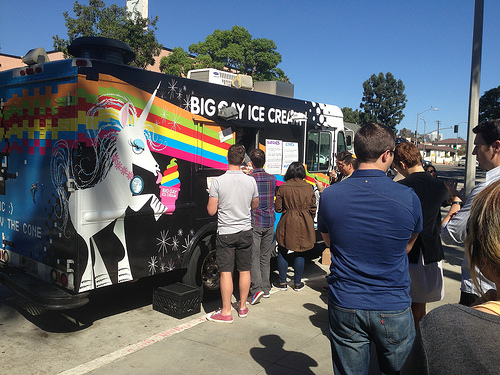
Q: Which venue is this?
A: This is a pavement.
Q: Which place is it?
A: It is a pavement.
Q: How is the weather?
A: It is clear.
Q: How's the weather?
A: It is clear.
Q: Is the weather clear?
A: Yes, it is clear.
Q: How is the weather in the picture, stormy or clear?
A: It is clear.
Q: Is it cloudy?
A: No, it is clear.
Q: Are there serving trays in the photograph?
A: No, there are no serving trays.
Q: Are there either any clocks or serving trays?
A: No, there are no serving trays or clocks.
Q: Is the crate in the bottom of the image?
A: Yes, the crate is in the bottom of the image.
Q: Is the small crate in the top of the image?
A: No, the crate is in the bottom of the image.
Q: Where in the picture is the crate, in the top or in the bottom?
A: The crate is in the bottom of the image.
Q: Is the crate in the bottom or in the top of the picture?
A: The crate is in the bottom of the image.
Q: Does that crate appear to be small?
A: Yes, the crate is small.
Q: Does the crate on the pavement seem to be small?
A: Yes, the crate is small.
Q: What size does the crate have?
A: The crate has small size.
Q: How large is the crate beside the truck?
A: The crate is small.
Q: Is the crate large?
A: No, the crate is small.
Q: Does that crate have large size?
A: No, the crate is small.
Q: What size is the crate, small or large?
A: The crate is small.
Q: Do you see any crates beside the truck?
A: Yes, there is a crate beside the truck.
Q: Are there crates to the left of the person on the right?
A: Yes, there is a crate to the left of the person.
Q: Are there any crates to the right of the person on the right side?
A: No, the crate is to the left of the person.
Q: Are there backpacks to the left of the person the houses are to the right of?
A: No, there is a crate to the left of the person.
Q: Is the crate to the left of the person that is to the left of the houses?
A: Yes, the crate is to the left of the person.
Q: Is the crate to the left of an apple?
A: No, the crate is to the left of the person.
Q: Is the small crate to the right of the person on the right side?
A: No, the crate is to the left of the person.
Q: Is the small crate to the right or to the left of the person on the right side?
A: The crate is to the left of the person.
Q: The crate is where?
A: The crate is on the pavement.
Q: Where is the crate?
A: The crate is on the pavement.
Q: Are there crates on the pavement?
A: Yes, there is a crate on the pavement.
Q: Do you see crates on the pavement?
A: Yes, there is a crate on the pavement.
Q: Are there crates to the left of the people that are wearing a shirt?
A: Yes, there is a crate to the left of the people.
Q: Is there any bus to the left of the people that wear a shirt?
A: No, there is a crate to the left of the people.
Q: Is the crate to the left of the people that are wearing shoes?
A: Yes, the crate is to the left of the people.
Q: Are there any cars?
A: No, there are no cars.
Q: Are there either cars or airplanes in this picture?
A: No, there are no cars or airplanes.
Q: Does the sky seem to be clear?
A: Yes, the sky is clear.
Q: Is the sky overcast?
A: No, the sky is clear.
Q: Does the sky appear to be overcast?
A: No, the sky is clear.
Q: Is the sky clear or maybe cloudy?
A: The sky is clear.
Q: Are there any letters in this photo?
A: Yes, there are letters.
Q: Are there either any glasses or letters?
A: Yes, there are letters.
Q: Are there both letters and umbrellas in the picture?
A: No, there are letters but no umbrellas.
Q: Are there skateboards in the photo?
A: No, there are no skateboards.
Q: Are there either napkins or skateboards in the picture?
A: No, there are no skateboards or napkins.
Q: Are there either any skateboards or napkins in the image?
A: No, there are no skateboards or napkins.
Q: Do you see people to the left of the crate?
A: No, the person is to the right of the crate.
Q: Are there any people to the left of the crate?
A: No, the person is to the right of the crate.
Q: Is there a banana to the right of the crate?
A: No, there is a person to the right of the crate.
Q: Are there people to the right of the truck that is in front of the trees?
A: Yes, there is a person to the right of the truck.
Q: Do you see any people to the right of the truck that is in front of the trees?
A: Yes, there is a person to the right of the truck.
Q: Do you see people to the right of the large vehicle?
A: Yes, there is a person to the right of the truck.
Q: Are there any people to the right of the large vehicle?
A: Yes, there is a person to the right of the truck.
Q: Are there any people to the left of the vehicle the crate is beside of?
A: No, the person is to the right of the truck.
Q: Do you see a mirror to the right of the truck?
A: No, there is a person to the right of the truck.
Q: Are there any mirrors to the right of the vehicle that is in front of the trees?
A: No, there is a person to the right of the truck.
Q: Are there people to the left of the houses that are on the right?
A: Yes, there is a person to the left of the houses.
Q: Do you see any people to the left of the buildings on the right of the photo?
A: Yes, there is a person to the left of the houses.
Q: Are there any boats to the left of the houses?
A: No, there is a person to the left of the houses.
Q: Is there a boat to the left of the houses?
A: No, there is a person to the left of the houses.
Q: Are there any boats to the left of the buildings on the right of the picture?
A: No, there is a person to the left of the houses.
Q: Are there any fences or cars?
A: No, there are no cars or fences.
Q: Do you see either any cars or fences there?
A: No, there are no cars or fences.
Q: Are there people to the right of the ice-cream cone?
A: Yes, there is a person to the right of the ice-cream cone.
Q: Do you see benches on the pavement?
A: No, there is a person on the pavement.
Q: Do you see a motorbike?
A: No, there are no motorcycles.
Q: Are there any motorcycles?
A: No, there are no motorcycles.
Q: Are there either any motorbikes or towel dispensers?
A: No, there are no motorbikes or towel dispensers.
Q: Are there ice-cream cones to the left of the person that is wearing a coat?
A: Yes, there is an ice-cream cone to the left of the person.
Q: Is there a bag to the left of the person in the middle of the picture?
A: No, there is an ice-cream cone to the left of the person.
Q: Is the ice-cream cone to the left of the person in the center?
A: Yes, the ice-cream cone is to the left of the person.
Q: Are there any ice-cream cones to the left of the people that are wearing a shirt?
A: Yes, there is an ice-cream cone to the left of the people.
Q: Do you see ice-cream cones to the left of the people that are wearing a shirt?
A: Yes, there is an ice-cream cone to the left of the people.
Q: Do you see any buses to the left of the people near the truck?
A: No, there is an ice-cream cone to the left of the people.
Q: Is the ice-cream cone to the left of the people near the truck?
A: Yes, the ice-cream cone is to the left of the people.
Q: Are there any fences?
A: No, there are no fences.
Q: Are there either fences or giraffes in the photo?
A: No, there are no fences or giraffes.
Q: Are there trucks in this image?
A: Yes, there is a truck.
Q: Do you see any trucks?
A: Yes, there is a truck.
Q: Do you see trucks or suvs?
A: Yes, there is a truck.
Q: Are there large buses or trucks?
A: Yes, there is a large truck.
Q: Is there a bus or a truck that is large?
A: Yes, the truck is large.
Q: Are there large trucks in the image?
A: Yes, there is a large truck.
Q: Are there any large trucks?
A: Yes, there is a large truck.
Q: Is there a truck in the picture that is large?
A: Yes, there is a truck that is large.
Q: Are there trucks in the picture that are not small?
A: Yes, there is a large truck.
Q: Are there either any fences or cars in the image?
A: No, there are no cars or fences.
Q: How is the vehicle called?
A: The vehicle is a truck.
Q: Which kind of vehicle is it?
A: The vehicle is a truck.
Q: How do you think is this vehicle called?
A: This is a truck.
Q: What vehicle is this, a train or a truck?
A: This is a truck.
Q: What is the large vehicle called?
A: The vehicle is a truck.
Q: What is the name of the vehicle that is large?
A: The vehicle is a truck.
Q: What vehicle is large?
A: The vehicle is a truck.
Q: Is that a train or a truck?
A: That is a truck.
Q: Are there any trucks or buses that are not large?
A: No, there is a truck but it is large.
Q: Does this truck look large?
A: Yes, the truck is large.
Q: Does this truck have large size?
A: Yes, the truck is large.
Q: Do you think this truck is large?
A: Yes, the truck is large.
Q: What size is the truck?
A: The truck is large.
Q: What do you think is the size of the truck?
A: The truck is large.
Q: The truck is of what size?
A: The truck is large.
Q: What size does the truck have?
A: The truck has large size.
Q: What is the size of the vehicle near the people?
A: The truck is large.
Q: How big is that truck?
A: The truck is large.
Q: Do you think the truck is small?
A: No, the truck is large.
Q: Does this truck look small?
A: No, the truck is large.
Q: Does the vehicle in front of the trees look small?
A: No, the truck is large.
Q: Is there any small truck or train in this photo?
A: No, there is a truck but it is large.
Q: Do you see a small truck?
A: No, there is a truck but it is large.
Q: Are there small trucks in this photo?
A: No, there is a truck but it is large.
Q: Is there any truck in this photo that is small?
A: No, there is a truck but it is large.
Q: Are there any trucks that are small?
A: No, there is a truck but it is large.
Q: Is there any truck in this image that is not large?
A: No, there is a truck but it is large.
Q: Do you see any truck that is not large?
A: No, there is a truck but it is large.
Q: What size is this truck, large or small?
A: The truck is large.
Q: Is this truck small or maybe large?
A: The truck is large.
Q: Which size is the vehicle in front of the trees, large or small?
A: The truck is large.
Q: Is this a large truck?
A: Yes, this is a large truck.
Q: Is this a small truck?
A: No, this is a large truck.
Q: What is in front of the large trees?
A: The truck is in front of the trees.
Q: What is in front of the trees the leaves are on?
A: The truck is in front of the trees.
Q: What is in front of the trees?
A: The truck is in front of the trees.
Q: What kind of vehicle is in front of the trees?
A: The vehicle is a truck.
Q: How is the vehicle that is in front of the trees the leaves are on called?
A: The vehicle is a truck.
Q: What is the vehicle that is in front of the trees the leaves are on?
A: The vehicle is a truck.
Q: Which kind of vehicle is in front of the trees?
A: The vehicle is a truck.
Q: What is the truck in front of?
A: The truck is in front of the trees.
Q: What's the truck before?
A: The truck is in front of the trees.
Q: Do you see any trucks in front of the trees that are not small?
A: Yes, there is a truck in front of the trees.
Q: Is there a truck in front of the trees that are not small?
A: Yes, there is a truck in front of the trees.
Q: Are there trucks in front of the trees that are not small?
A: Yes, there is a truck in front of the trees.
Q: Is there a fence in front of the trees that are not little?
A: No, there is a truck in front of the trees.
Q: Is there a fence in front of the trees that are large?
A: No, there is a truck in front of the trees.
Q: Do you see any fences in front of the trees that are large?
A: No, there is a truck in front of the trees.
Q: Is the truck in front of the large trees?
A: Yes, the truck is in front of the trees.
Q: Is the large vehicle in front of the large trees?
A: Yes, the truck is in front of the trees.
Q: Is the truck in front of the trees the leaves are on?
A: Yes, the truck is in front of the trees.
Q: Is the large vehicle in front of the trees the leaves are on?
A: Yes, the truck is in front of the trees.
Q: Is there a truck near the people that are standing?
A: Yes, there is a truck near the people.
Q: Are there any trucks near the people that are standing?
A: Yes, there is a truck near the people.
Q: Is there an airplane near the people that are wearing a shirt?
A: No, there is a truck near the people.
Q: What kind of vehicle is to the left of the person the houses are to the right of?
A: The vehicle is a truck.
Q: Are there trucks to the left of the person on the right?
A: Yes, there is a truck to the left of the person.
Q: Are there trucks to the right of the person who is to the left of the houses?
A: No, the truck is to the left of the person.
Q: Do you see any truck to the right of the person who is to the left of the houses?
A: No, the truck is to the left of the person.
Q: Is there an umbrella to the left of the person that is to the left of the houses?
A: No, there is a truck to the left of the person.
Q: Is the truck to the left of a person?
A: Yes, the truck is to the left of a person.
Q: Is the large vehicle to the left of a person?
A: Yes, the truck is to the left of a person.